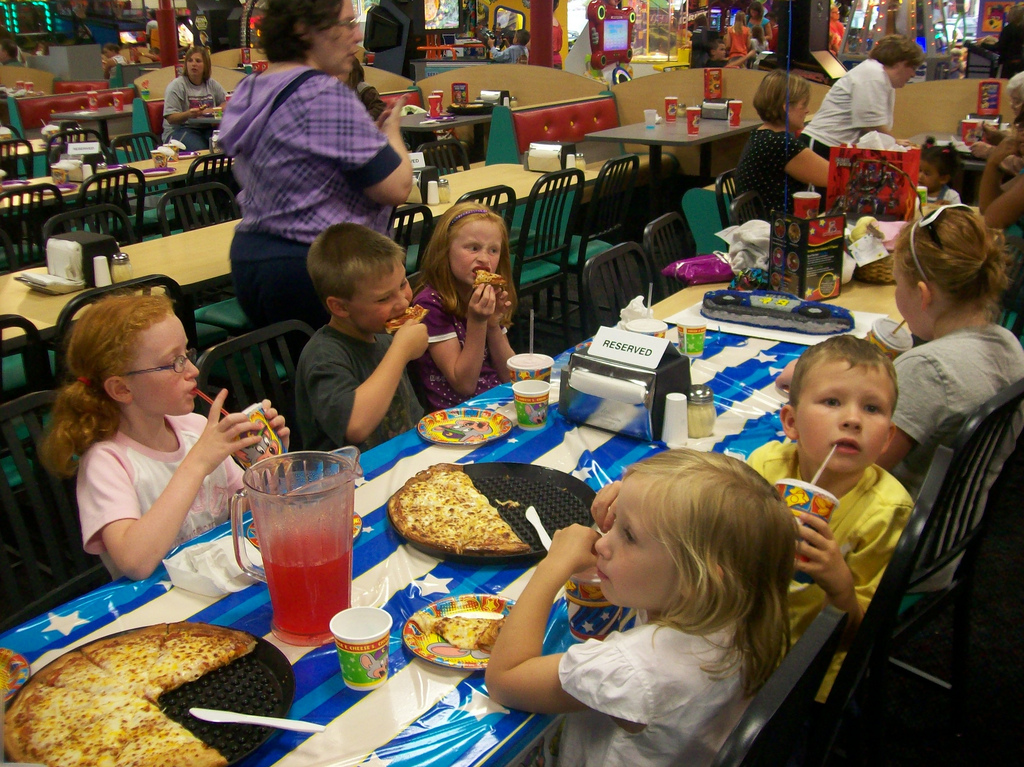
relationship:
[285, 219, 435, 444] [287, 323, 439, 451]
boy with a shirt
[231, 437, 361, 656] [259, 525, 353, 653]
pitcher of drink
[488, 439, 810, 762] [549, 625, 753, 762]
girl in shirt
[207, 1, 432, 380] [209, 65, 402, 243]
woman with shirt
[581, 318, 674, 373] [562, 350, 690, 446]
sign on napkin holder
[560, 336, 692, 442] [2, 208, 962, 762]
napkin holder on table